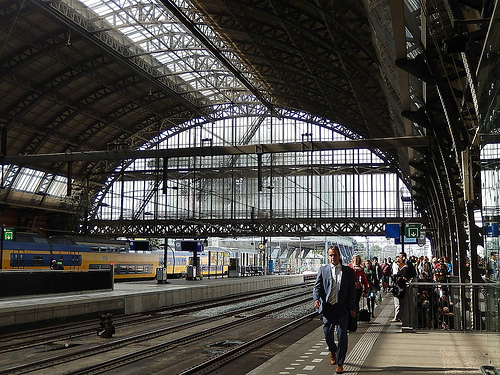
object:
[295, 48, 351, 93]
section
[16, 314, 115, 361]
section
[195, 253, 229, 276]
section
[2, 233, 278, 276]
train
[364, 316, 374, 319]
part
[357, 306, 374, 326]
bag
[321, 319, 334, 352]
leg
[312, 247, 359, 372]
man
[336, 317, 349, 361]
leg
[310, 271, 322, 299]
arm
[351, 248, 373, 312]
woman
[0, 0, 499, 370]
station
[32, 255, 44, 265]
window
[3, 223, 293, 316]
substation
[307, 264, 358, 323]
suit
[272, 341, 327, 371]
sidewalk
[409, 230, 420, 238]
arrow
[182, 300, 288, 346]
sets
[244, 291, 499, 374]
platform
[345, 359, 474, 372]
shadow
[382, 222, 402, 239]
flag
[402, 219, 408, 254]
pole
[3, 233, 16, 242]
light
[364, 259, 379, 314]
people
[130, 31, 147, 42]
lights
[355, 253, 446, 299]
crowd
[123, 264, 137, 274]
windows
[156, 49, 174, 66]
skylights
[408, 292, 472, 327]
stairwell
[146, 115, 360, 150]
bars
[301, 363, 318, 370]
squares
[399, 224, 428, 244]
signs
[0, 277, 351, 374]
rail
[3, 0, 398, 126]
dome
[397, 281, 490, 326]
barricade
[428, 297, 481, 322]
stairs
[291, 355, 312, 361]
lines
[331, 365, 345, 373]
shoes